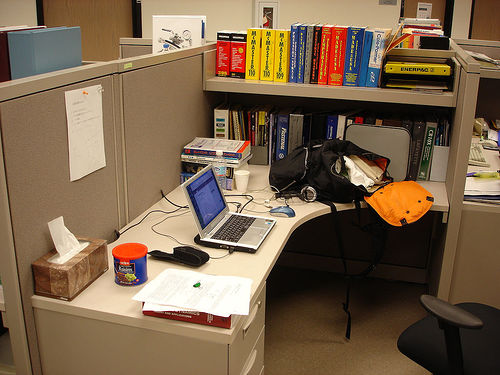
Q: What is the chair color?
A: Black.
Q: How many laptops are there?
A: One.